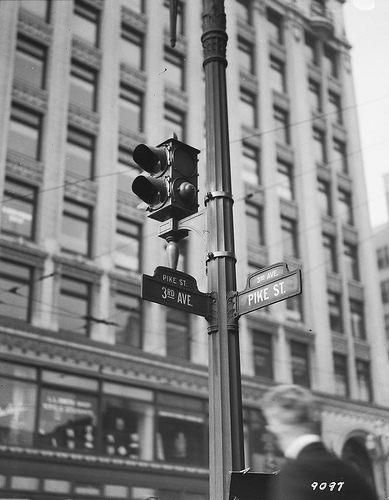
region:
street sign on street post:
[144, 265, 209, 329]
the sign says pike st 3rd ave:
[144, 263, 210, 325]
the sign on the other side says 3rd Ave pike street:
[235, 264, 312, 309]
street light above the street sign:
[124, 142, 206, 227]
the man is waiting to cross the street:
[244, 378, 378, 498]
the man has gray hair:
[255, 386, 337, 436]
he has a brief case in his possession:
[225, 467, 273, 498]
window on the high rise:
[64, 194, 90, 254]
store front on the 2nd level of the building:
[4, 361, 159, 457]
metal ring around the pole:
[205, 192, 234, 203]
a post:
[91, 160, 249, 361]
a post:
[109, 340, 341, 490]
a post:
[156, 345, 252, 496]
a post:
[142, 253, 285, 497]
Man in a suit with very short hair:
[253, 377, 376, 498]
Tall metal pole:
[176, 25, 264, 490]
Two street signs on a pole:
[128, 253, 313, 334]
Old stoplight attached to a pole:
[125, 125, 250, 255]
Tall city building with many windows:
[0, 13, 135, 447]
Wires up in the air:
[243, 103, 369, 244]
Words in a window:
[25, 384, 114, 458]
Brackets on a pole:
[191, 176, 242, 272]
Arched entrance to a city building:
[310, 371, 387, 494]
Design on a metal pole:
[169, 3, 239, 91]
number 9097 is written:
[317, 478, 334, 488]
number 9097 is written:
[319, 475, 329, 490]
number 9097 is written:
[323, 478, 331, 497]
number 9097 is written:
[317, 484, 328, 490]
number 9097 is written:
[310, 475, 325, 494]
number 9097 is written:
[316, 473, 336, 497]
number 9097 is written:
[334, 487, 344, 491]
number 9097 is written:
[310, 482, 331, 493]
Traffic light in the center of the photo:
[130, 129, 208, 228]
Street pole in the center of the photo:
[172, 0, 264, 499]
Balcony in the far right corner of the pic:
[290, 1, 358, 64]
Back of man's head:
[237, 374, 387, 497]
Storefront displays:
[1, 366, 229, 482]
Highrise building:
[4, 2, 384, 472]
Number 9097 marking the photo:
[298, 472, 379, 499]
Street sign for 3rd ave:
[120, 252, 214, 330]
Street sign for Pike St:
[234, 253, 336, 334]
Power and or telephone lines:
[1, 120, 384, 341]